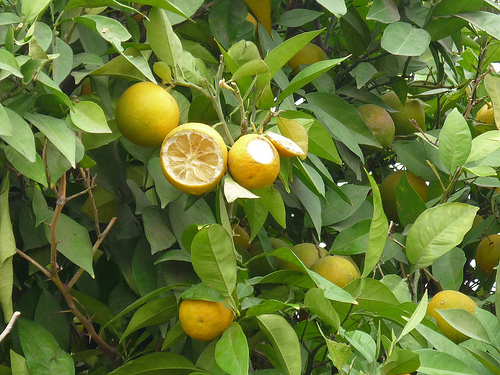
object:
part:
[245, 135, 277, 164]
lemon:
[425, 288, 476, 345]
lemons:
[287, 42, 329, 71]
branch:
[12, 129, 120, 360]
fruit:
[227, 131, 281, 188]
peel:
[264, 130, 306, 156]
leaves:
[68, 100, 113, 135]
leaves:
[33, 92, 70, 116]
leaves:
[0, 97, 15, 137]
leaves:
[5, 143, 48, 187]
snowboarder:
[157, 122, 228, 197]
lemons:
[352, 102, 395, 147]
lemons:
[378, 169, 429, 225]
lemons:
[475, 234, 498, 270]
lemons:
[379, 90, 423, 140]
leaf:
[68, 99, 113, 135]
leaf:
[22, 110, 76, 171]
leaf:
[1, 106, 36, 164]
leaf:
[41, 206, 96, 279]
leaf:
[31, 69, 78, 114]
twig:
[56, 287, 118, 357]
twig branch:
[63, 164, 123, 288]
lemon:
[178, 297, 234, 341]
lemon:
[310, 251, 359, 288]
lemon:
[287, 42, 329, 77]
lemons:
[424, 290, 479, 344]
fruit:
[116, 80, 179, 149]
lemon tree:
[0, 0, 499, 373]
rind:
[244, 137, 276, 165]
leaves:
[0, 48, 26, 79]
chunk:
[159, 120, 227, 194]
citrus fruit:
[159, 122, 227, 195]